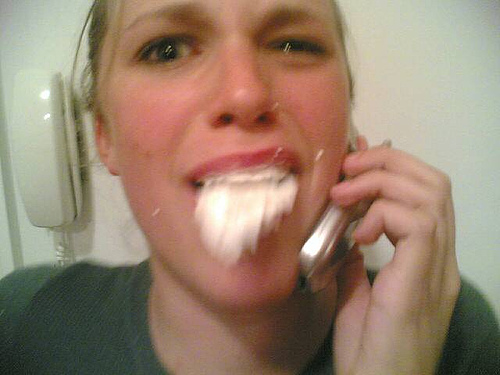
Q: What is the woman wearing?
A: Green shirt.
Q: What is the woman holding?
A: A phone.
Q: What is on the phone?
A: Two fingers.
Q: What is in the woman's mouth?
A: White foam.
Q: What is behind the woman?
A: A wall.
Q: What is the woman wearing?
A: A green shirt.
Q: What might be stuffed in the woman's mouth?
A: Cotton.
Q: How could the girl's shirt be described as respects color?
A: Olive green.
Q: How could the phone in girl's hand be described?
A: Silver.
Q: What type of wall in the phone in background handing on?
A: White.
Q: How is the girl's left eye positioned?
A: Partially closed.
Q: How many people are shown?
A: One.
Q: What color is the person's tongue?
A: White.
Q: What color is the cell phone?
A: Silver.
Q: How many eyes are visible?
A: Two.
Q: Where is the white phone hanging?
A: On wall.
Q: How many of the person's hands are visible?
A: One.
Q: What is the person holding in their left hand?
A: Cell Phone.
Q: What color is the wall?
A: White.